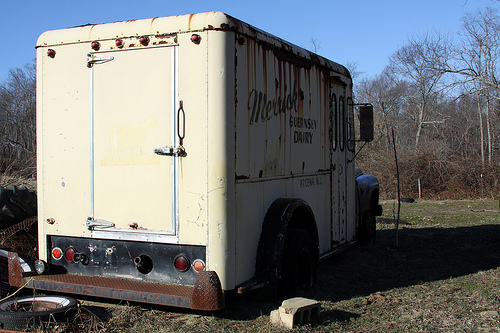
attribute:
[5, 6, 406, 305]
truck — old, rusty, white, beige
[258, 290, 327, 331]
brick — grey, broken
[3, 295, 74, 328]
tire — old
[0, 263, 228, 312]
bumper — rusty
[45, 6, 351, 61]
roof — rusting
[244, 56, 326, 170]
writing — faded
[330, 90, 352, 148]
windows — oval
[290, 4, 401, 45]
sky — blue